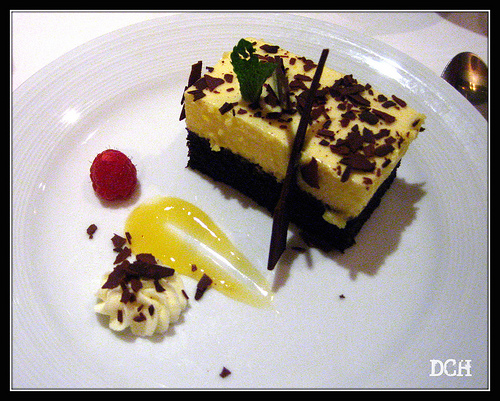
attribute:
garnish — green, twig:
[231, 36, 279, 106]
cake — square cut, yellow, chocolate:
[181, 130, 426, 251]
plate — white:
[11, 10, 498, 399]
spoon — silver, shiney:
[443, 48, 488, 116]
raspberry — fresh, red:
[88, 147, 140, 202]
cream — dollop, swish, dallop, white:
[93, 259, 192, 342]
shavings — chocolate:
[101, 251, 178, 299]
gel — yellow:
[125, 196, 269, 319]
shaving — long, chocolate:
[263, 48, 329, 277]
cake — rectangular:
[178, 34, 427, 270]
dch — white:
[427, 353, 478, 384]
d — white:
[427, 355, 444, 384]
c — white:
[443, 356, 458, 381]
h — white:
[457, 356, 475, 381]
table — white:
[13, 10, 494, 90]